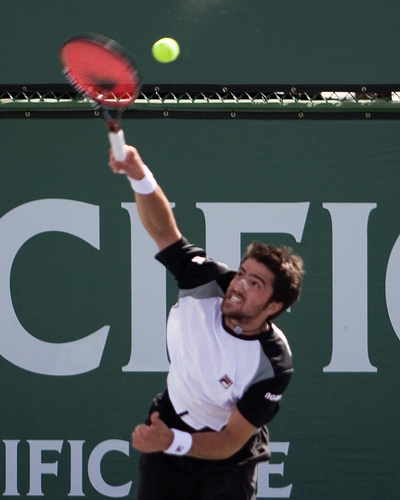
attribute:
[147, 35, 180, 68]
tennis ball — bright green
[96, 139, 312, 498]
man —  playing tennis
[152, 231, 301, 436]
tee shirt — black, white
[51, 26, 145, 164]
tennis racket — red, white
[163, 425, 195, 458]
wrist band — bright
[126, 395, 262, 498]
shorts — plain, black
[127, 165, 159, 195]
wristband — white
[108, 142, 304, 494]
man — white, black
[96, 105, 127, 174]
handle — white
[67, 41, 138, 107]
strings — red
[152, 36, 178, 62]
ball — yellow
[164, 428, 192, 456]
wristband — white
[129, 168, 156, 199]
wristband — white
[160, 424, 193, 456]
wristband — white